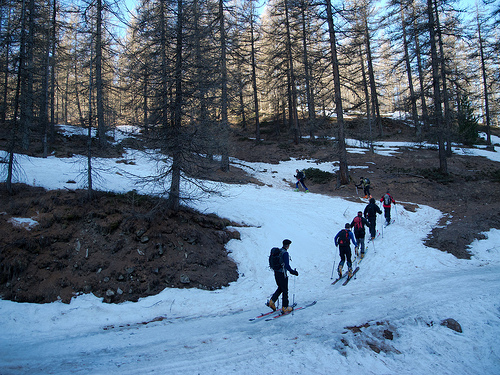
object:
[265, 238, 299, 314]
person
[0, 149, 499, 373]
snow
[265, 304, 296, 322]
ski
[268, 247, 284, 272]
backpack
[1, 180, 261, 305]
dirt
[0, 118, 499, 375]
hil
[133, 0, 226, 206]
tree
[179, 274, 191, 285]
stone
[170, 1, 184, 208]
stem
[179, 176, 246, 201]
branch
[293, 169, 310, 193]
person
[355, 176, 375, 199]
person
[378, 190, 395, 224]
person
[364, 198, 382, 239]
person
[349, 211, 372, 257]
person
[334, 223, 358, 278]
person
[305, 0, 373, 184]
tree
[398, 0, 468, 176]
tree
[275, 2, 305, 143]
tree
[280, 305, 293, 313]
boot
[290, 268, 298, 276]
glove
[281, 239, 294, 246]
hat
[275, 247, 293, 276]
coat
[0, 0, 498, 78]
sky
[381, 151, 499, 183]
dirt